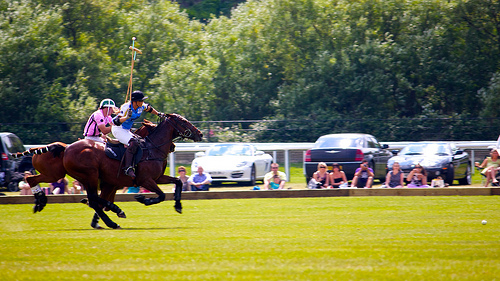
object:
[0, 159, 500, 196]
parking lot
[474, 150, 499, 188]
woman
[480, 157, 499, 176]
shirt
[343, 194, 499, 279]
field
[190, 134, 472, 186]
car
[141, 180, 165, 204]
leg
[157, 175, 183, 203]
leg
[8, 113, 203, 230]
horse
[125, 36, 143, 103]
mallet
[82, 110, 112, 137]
pink shirt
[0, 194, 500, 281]
grass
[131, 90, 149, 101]
helmet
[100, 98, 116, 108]
helmet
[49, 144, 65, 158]
hair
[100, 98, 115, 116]
head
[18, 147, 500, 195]
people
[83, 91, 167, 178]
man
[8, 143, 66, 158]
tail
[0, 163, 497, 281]
ground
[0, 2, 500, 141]
trees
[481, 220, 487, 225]
ball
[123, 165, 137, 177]
foot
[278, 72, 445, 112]
leaves